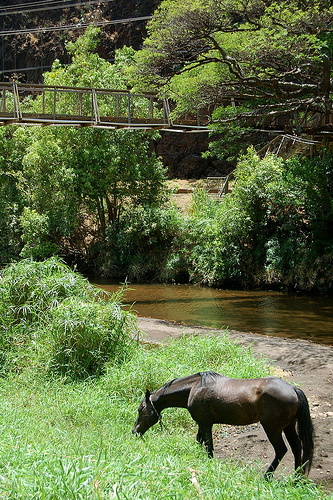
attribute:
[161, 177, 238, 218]
floor — brown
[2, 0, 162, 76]
electric wires — above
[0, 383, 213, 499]
plant — green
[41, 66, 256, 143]
bridge — connecting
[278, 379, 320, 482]
tail — fluffy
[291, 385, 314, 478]
tail — long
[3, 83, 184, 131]
bridge — wooden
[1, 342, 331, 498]
grass — long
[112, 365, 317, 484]
horse — grazing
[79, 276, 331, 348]
water — colorless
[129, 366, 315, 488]
horse — brown, grazing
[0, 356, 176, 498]
grass — tall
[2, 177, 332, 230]
terrain — across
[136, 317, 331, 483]
ground area — bare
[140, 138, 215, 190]
area — walled